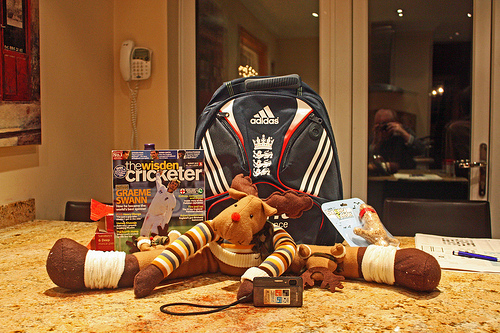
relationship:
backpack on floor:
[199, 111, 301, 168] [65, 189, 77, 195]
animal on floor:
[225, 207, 261, 225] [65, 189, 77, 195]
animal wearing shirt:
[225, 207, 261, 225] [204, 249, 289, 268]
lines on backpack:
[303, 151, 325, 162] [199, 111, 301, 168]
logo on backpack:
[247, 115, 268, 125] [199, 111, 301, 168]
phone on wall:
[119, 39, 156, 92] [129, 16, 149, 37]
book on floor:
[110, 149, 205, 255] [65, 189, 77, 195]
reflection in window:
[256, 39, 266, 43] [221, 38, 261, 64]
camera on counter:
[202, 149, 232, 173] [60, 310, 84, 319]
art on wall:
[0, 58, 47, 116] [129, 16, 149, 37]